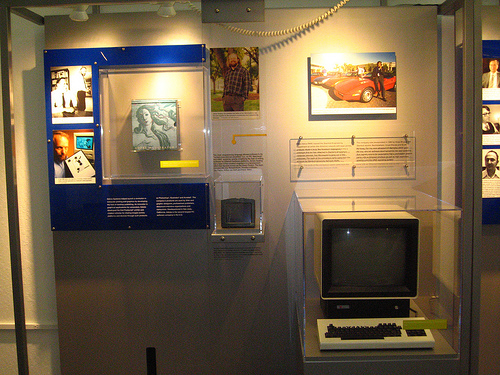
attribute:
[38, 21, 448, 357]
wall — white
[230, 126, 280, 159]
cord — yellow, coiled, white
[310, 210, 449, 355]
computer — old, white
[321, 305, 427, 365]
keyboard — black, old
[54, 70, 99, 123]
picture — white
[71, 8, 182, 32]
lights — white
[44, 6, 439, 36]
ceiling — hung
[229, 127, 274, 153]
arrow — yellow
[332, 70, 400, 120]
car — red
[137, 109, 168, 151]
woman — white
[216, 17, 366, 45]
wire — spiraled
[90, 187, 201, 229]
display — blue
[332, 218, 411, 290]
monitor — display, small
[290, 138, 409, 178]
box — clear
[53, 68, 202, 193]
pictures — three